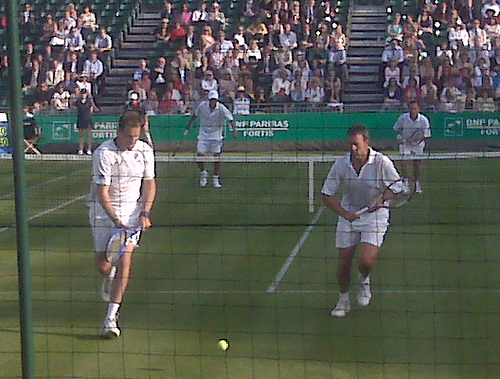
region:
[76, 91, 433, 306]
Tennis players on the court.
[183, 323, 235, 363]
The yellow ball is in the air.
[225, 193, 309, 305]
White line on the court.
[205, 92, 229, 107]
The player is wearing a white cap.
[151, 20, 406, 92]
People watching the match.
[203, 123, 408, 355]
The player is running toward the ball.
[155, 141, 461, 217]
A black net across the court.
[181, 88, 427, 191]
Two men on the other side of the court.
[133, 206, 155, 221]
The man is wearing a wristband.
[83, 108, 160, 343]
Man running for a tennis ball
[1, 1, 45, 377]
Green pole on a tennis court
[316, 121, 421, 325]
Man running with a tennis racket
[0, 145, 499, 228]
Net separating the tennis court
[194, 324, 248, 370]
Bouncing green tennis ball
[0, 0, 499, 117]
Bunch of people watching a tennis match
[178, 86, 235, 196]
Man dressed in all white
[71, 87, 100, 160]
Lady standing by a sign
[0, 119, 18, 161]
Corner of the score board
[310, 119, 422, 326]
person playing tennis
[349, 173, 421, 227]
tennis racket in a persons hand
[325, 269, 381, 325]
two white shoes on a persons feet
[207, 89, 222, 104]
white hat on a persons head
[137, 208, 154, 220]
watch on a persons wrist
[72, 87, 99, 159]
person with a black shirt standing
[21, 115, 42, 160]
chair on the ground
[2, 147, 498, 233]
net on a tennis court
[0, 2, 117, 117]
spectators in stands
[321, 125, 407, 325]
this is a person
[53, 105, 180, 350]
this is a person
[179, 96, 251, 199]
this is a person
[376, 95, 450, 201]
this is a person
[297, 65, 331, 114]
this is a person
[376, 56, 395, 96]
this is a person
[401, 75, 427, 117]
this is a person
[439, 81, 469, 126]
this is a person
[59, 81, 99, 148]
this is a person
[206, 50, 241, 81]
this is a person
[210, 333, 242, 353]
green tennis ball in air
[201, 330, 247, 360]
green tennis ball in air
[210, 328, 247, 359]
green tennis ball in air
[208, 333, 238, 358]
green tennis ball in air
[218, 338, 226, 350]
tennis ball on the ground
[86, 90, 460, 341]
the is men's doubles on the court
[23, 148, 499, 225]
white edged tennis net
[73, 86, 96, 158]
tennis umpire dressed in black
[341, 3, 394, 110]
steps up the bleachers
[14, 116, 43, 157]
a director's chair at courtside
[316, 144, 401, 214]
white polo shirt on a player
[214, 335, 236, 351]
a small green tennis ball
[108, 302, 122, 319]
a man's white sock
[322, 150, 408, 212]
a man's white shirt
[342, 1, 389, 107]
a stadium staircase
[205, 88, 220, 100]
a white baseball cap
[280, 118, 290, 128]
a white capital letter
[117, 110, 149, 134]
a man's short cut hair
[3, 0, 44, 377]
a tall green pole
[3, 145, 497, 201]
a long black and white net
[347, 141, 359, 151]
the nose of a man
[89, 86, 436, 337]
four tennis players playing a game of doubles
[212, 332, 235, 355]
yellow tennis ball in flight